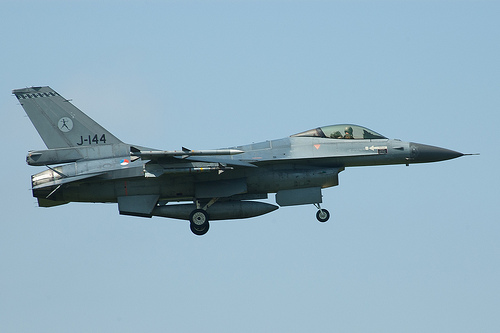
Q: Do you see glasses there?
A: No, there are no glasses.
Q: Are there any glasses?
A: No, there are no glasses.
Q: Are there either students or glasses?
A: No, there are no glasses or students.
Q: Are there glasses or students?
A: No, there are no glasses or students.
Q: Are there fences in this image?
A: No, there are no fences.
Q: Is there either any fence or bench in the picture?
A: No, there are no fences or benches.